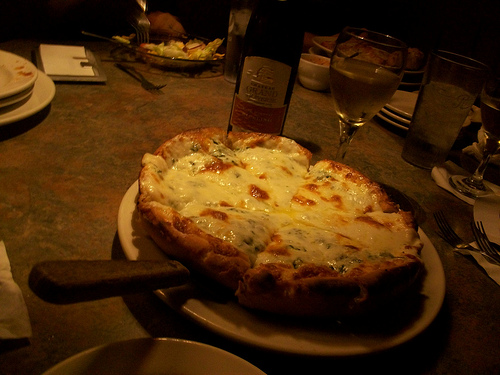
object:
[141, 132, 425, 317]
pizza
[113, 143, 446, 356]
plate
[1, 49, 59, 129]
plates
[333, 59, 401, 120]
wine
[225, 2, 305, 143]
bottle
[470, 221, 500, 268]
forks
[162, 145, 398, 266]
cheese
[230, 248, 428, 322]
crust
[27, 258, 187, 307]
handle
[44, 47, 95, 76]
paper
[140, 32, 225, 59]
salad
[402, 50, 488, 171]
cup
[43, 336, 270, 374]
bowl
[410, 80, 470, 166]
water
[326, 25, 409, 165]
glass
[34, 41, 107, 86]
board